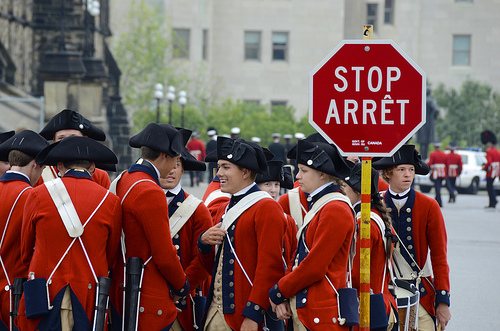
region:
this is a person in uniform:
[365, 137, 470, 326]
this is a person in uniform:
[271, 133, 356, 328]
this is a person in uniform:
[195, 148, 285, 325]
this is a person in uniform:
[120, 143, 211, 328]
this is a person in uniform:
[23, 137, 137, 324]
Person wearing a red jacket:
[285, 138, 356, 325]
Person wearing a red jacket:
[375, 142, 445, 329]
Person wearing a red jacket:
[210, 131, 277, 318]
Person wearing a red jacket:
[115, 111, 182, 323]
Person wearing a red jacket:
[5, 124, 133, 329]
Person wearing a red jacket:
[474, 119, 496, 224]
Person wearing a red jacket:
[445, 138, 461, 210]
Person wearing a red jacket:
[426, 137, 452, 197]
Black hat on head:
[48, 130, 124, 192]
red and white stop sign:
[312, 45, 425, 165]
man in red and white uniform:
[23, 132, 128, 314]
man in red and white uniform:
[116, 116, 188, 323]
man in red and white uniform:
[282, 145, 352, 324]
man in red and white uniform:
[386, 150, 451, 327]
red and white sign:
[306, 34, 431, 159]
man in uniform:
[29, 134, 119, 311]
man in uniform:
[282, 138, 362, 316]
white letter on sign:
[332, 63, 351, 93]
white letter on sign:
[352, 65, 363, 94]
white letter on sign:
[368, 66, 383, 92]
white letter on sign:
[385, 63, 400, 92]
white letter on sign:
[324, 98, 341, 123]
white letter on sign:
[342, 98, 359, 123]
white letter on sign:
[361, 98, 377, 125]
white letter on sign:
[381, 98, 394, 125]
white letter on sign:
[395, 98, 410, 124]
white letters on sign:
[321, 64, 411, 129]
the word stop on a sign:
[335, 63, 402, 93]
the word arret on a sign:
[325, 93, 411, 130]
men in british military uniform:
[0, 108, 450, 328]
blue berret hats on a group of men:
[0, 113, 437, 193]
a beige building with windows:
[8, 0, 497, 167]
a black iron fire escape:
[2, 0, 131, 154]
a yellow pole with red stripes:
[357, 154, 372, 328]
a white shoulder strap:
[214, 188, 277, 231]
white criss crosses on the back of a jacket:
[30, 180, 116, 313]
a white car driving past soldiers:
[414, 145, 499, 187]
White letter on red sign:
[330, 61, 350, 98]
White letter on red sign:
[348, 61, 365, 98]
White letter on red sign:
[367, 59, 385, 96]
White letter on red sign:
[383, 62, 400, 92]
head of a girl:
[243, 131, 360, 225]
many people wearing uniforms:
[1, 137, 417, 294]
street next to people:
[452, 219, 492, 268]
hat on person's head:
[192, 128, 278, 181]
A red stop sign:
[306, 33, 437, 160]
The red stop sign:
[301, 35, 436, 162]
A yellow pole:
[345, 157, 393, 328]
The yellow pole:
[349, 155, 388, 329]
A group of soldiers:
[1, 97, 471, 327]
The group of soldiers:
[7, 120, 449, 312]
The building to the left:
[1, 0, 150, 170]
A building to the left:
[1, 0, 145, 175]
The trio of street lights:
[138, 70, 198, 125]